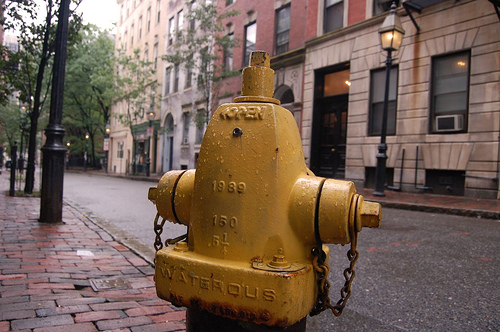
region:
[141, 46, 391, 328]
Yellow fire hydrant on street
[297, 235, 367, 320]
Chain for yellow fire hydrant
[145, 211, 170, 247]
Chain for yellow fire hydrant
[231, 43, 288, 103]
Top os yellow fire hydrant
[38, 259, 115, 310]
Part of brick paved sidewalk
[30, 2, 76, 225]
Metal pole for street light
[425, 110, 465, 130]
Air conditioner in window of building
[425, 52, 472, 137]
Window of nearby building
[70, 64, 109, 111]
Part of green trees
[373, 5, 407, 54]
Street light at top of pole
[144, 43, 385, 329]
a yellow fire hydrant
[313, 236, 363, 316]
rusty chain on a fire hydrant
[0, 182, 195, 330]
the paved sidewalk is uneven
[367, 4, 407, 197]
a street lamp is on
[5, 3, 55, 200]
trees grow up out of the sidewalk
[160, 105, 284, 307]
raised numbers and letters on a fire hydrant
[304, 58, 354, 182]
a light is on over a door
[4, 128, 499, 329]
the street is deserted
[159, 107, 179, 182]
an arched stone doorway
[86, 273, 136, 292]
a drain cover in the sidewalk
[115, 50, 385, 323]
A yellow fire hydrant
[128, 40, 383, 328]
A yellow fire hydrant on the pavement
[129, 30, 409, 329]
A yellow fire hydrant next t the street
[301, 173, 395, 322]
a chain on the side of a fire hydrant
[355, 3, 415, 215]
a lit street light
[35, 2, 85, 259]
The bottom part of a street light pole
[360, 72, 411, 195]
The bottom part of a black street light pole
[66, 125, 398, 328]
a roadway next to a fire hydrant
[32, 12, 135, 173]
trees on the side of a building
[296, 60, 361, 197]
a large door with glass on top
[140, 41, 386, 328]
yellow fire hydrant on the street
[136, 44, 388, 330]
fire hydrant is rusty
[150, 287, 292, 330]
rust on fire hydrant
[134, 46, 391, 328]
caps on fire hydrant are held on with chains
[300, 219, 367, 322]
chain holding cap of fire hydrant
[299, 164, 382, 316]
cap on fire hydrant with connected chain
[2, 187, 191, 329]
uneven brick walkway next to hydrant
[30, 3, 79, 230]
tall black light pole near fire hydrant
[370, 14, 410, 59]
light on light pole is turned on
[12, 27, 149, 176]
trees in background near building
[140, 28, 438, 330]
this is a fire hydrant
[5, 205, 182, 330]
a brick side walk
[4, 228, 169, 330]
the sidewalk is laid with brick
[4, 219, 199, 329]
a red brick sidewalk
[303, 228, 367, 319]
chain on the hydrant cap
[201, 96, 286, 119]
this says "OPEN"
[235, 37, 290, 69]
bolt on top of the hydrant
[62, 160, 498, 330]
a narrow city street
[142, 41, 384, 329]
the fire hydrant is wet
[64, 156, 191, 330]
the sidewalk and street are both wet